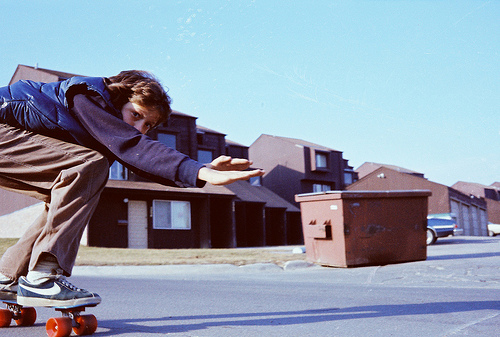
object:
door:
[451, 195, 465, 229]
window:
[151, 198, 192, 230]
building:
[0, 65, 297, 249]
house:
[4, 63, 300, 249]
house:
[247, 133, 360, 242]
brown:
[296, 191, 433, 268]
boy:
[0, 65, 265, 311]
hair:
[104, 69, 172, 128]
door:
[127, 200, 152, 251]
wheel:
[16, 303, 37, 327]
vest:
[0, 66, 112, 131]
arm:
[73, 93, 201, 187]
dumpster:
[294, 188, 434, 269]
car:
[425, 213, 459, 248]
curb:
[72, 260, 311, 276]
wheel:
[71, 313, 96, 332]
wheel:
[1, 309, 11, 324]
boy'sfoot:
[15, 269, 104, 309]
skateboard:
[0, 290, 110, 337]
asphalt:
[183, 279, 350, 332]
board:
[0, 292, 96, 337]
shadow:
[100, 292, 499, 334]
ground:
[0, 267, 497, 337]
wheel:
[73, 317, 107, 335]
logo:
[13, 281, 66, 295]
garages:
[344, 165, 489, 235]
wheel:
[46, 314, 73, 335]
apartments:
[245, 133, 357, 208]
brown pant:
[0, 116, 113, 278]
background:
[0, 0, 499, 254]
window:
[315, 155, 329, 168]